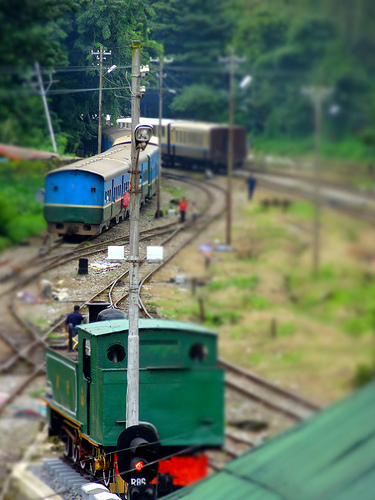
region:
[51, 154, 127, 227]
this is a train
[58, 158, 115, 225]
the train is long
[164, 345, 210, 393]
the head is green in color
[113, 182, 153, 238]
this is a pole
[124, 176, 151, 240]
the pole is straight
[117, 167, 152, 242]
the pole is metallic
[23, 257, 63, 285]
these are the rails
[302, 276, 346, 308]
these are the grass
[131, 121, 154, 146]
the light is off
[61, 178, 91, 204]
the train is blue in color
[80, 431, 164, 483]
the light is on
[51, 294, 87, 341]
a person on the railway line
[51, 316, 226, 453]
the train is green in colour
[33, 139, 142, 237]
the train is blue in colour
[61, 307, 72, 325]
the shirt is blue in colour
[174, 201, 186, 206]
the shirt is red in colour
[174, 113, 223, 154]
the train is brown in colour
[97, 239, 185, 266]
barriers on the rail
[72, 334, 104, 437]
the door is open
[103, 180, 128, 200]
the train has windows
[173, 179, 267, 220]
People standing on the track.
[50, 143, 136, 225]
A blue train on the track.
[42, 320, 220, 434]
A green train car on the tracks.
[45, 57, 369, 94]
Wires on the pole.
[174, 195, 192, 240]
Person is wearing a red shirt.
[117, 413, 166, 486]
Train signals on the pole.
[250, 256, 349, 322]
Green trees in the middle of tracks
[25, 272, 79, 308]
Trash on the tracks.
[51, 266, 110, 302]
Gravel in between the tracks.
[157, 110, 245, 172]
A brown train car on the tracks.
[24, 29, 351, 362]
the scene is at a railway crossway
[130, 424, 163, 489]
the light plates are black in color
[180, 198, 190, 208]
the shirt is red in color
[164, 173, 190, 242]
the man standing behind the trains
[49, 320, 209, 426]
train cab is green in color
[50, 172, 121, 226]
the train is mettalic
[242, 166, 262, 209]
the man in a light blue outfit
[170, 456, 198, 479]
train cab is red in color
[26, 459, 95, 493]
the plates are silver cemented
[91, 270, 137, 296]
the rocks are grey in color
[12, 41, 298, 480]
a toy model train set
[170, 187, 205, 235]
figurine of a train worker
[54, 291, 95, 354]
a figure of a person wearing blue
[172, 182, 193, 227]
figure of a person wearing a red shirt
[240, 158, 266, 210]
a figure of a person wearing blue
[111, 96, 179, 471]
a toy light pole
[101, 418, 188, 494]
a toy train crossing sign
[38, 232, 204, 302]
train tracks for the toy train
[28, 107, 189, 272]
parked blue and green train cars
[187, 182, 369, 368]
grass in a toy train yard